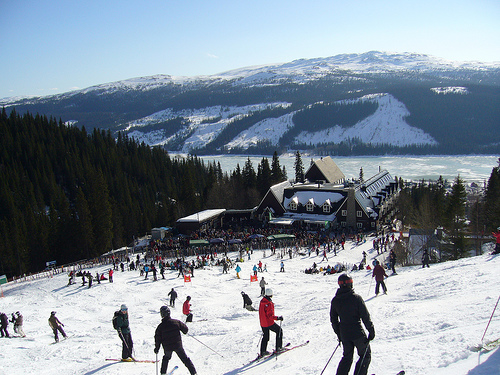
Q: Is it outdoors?
A: Yes, it is outdoors.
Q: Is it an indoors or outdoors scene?
A: It is outdoors.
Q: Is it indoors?
A: No, it is outdoors.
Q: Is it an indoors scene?
A: No, it is outdoors.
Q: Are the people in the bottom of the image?
A: Yes, the people are in the bottom of the image.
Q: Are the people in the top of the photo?
A: No, the people are in the bottom of the image.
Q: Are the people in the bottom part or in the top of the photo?
A: The people are in the bottom of the image.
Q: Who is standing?
A: The people are standing.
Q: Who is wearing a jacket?
A: The people are wearing a jacket.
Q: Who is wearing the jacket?
A: The people are wearing a jacket.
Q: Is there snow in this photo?
A: Yes, there is snow.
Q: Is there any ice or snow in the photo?
A: Yes, there is snow.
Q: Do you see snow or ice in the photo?
A: Yes, there is snow.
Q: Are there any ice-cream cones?
A: No, there are no ice-cream cones.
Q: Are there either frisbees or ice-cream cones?
A: No, there are no ice-cream cones or frisbees.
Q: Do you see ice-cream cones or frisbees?
A: No, there are no ice-cream cones or frisbees.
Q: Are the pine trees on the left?
A: Yes, the pine trees are on the left of the image.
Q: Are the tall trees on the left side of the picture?
A: Yes, the pine trees are on the left of the image.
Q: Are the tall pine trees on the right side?
A: No, the pine trees are on the left of the image.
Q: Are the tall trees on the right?
A: No, the pine trees are on the left of the image.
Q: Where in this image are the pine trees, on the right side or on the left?
A: The pine trees are on the left of the image.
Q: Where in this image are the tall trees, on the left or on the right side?
A: The pine trees are on the left of the image.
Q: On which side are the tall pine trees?
A: The pines are on the left of the image.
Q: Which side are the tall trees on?
A: The pines are on the left of the image.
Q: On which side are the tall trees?
A: The pines are on the left of the image.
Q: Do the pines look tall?
A: Yes, the pines are tall.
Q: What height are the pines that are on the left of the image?
A: The pine trees are tall.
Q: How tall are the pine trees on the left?
A: The pine trees are tall.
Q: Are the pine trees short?
A: No, the pine trees are tall.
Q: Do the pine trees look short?
A: No, the pine trees are tall.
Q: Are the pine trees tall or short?
A: The pine trees are tall.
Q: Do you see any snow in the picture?
A: Yes, there is snow.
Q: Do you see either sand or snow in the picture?
A: Yes, there is snow.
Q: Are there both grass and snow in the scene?
A: No, there is snow but no grass.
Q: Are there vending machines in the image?
A: No, there are no vending machines.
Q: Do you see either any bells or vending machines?
A: No, there are no vending machines or bells.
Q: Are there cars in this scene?
A: No, there are no cars.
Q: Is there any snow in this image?
A: Yes, there is snow.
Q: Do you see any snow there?
A: Yes, there is snow.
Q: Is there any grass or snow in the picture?
A: Yes, there is snow.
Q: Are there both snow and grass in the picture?
A: No, there is snow but no grass.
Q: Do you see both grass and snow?
A: No, there is snow but no grass.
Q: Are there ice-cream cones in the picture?
A: No, there are no ice-cream cones.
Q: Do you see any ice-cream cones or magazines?
A: No, there are no ice-cream cones or magazines.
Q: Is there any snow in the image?
A: Yes, there is snow.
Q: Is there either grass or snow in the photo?
A: Yes, there is snow.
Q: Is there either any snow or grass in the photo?
A: Yes, there is snow.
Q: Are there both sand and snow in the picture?
A: No, there is snow but no sand.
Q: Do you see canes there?
A: No, there are no canes.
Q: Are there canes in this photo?
A: No, there are no canes.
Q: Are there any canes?
A: No, there are no canes.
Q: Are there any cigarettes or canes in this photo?
A: No, there are no canes or cigarettes.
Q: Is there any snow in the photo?
A: Yes, there is snow.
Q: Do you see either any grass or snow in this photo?
A: Yes, there is snow.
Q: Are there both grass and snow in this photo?
A: No, there is snow but no grass.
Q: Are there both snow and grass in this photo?
A: No, there is snow but no grass.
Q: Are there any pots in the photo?
A: No, there are no pots.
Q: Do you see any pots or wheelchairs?
A: No, there are no pots or wheelchairs.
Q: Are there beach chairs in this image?
A: No, there are no beach chairs.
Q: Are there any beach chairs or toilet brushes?
A: No, there are no beach chairs or toilet brushes.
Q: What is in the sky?
A: The clouds are in the sky.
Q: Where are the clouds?
A: The clouds are in the sky.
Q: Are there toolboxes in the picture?
A: No, there are no toolboxes.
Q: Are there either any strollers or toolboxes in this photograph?
A: No, there are no toolboxes or strollers.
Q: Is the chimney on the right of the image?
A: Yes, the chimney is on the right of the image.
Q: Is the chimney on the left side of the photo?
A: No, the chimney is on the right of the image.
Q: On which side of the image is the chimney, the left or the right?
A: The chimney is on the right of the image.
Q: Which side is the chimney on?
A: The chimney is on the right of the image.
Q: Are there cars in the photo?
A: No, there are no cars.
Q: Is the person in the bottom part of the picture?
A: Yes, the person is in the bottom of the image.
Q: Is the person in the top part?
A: No, the person is in the bottom of the image.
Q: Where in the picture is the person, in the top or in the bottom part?
A: The person is in the bottom of the image.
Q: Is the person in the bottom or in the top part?
A: The person is in the bottom of the image.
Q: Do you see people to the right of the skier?
A: Yes, there is a person to the right of the skier.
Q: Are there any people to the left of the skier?
A: No, the person is to the right of the skier.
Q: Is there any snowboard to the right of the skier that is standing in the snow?
A: No, there is a person to the right of the skier.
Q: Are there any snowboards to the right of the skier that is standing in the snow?
A: No, there is a person to the right of the skier.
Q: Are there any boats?
A: No, there are no boats.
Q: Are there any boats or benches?
A: No, there are no boats or benches.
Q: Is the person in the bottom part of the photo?
A: Yes, the person is in the bottom of the image.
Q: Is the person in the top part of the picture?
A: No, the person is in the bottom of the image.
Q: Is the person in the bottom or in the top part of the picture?
A: The person is in the bottom of the image.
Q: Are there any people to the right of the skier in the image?
A: Yes, there is a person to the right of the skier.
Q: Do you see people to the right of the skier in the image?
A: Yes, there is a person to the right of the skier.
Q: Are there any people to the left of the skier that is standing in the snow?
A: No, the person is to the right of the skier.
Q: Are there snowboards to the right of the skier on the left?
A: No, there is a person to the right of the skier.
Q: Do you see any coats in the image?
A: Yes, there is a coat.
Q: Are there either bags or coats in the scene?
A: Yes, there is a coat.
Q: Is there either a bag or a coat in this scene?
A: Yes, there is a coat.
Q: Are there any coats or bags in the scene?
A: Yes, there is a coat.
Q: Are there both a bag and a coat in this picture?
A: No, there is a coat but no bags.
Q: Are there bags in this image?
A: No, there are no bags.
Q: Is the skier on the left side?
A: Yes, the skier is on the left of the image.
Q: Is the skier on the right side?
A: No, the skier is on the left of the image.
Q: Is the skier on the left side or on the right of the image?
A: The skier is on the left of the image.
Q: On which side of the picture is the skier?
A: The skier is on the left of the image.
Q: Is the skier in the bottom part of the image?
A: Yes, the skier is in the bottom of the image.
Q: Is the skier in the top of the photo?
A: No, the skier is in the bottom of the image.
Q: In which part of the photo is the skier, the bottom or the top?
A: The skier is in the bottom of the image.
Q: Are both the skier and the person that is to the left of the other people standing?
A: Yes, both the skier and the person are standing.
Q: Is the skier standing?
A: Yes, the skier is standing.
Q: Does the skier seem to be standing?
A: Yes, the skier is standing.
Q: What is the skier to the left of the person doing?
A: The skier is standing.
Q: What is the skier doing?
A: The skier is standing.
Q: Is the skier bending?
A: No, the skier is standing.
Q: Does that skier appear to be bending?
A: No, the skier is standing.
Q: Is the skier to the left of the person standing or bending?
A: The skier is standing.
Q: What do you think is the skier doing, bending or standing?
A: The skier is standing.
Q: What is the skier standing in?
A: The skier is standing in the snow.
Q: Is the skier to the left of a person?
A: Yes, the skier is to the left of a person.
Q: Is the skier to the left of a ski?
A: No, the skier is to the left of a person.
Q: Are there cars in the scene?
A: No, there are no cars.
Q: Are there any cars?
A: No, there are no cars.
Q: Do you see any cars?
A: No, there are no cars.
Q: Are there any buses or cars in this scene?
A: No, there are no cars or buses.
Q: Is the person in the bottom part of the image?
A: Yes, the person is in the bottom of the image.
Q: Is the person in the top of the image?
A: No, the person is in the bottom of the image.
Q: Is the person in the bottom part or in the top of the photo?
A: The person is in the bottom of the image.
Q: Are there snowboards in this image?
A: No, there are no snowboards.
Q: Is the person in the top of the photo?
A: No, the person is in the bottom of the image.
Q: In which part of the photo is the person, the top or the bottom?
A: The person is in the bottom of the image.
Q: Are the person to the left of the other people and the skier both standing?
A: Yes, both the person and the skier are standing.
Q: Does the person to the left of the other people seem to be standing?
A: Yes, the person is standing.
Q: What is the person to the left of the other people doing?
A: The person is standing.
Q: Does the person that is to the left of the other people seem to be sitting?
A: No, the person is standing.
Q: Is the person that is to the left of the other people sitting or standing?
A: The person is standing.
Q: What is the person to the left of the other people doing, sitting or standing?
A: The person is standing.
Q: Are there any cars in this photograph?
A: No, there are no cars.